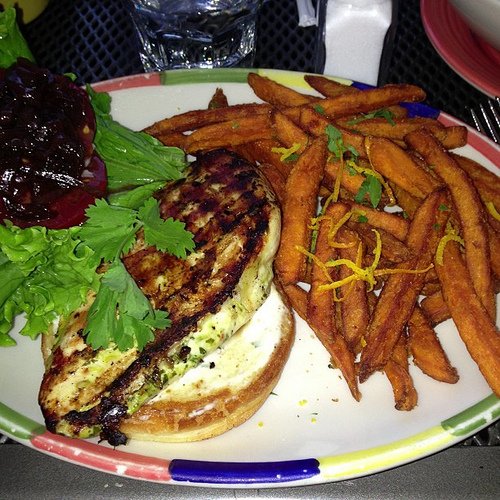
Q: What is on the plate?
A: The fries are on the plate.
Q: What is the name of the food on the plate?
A: The food is fries.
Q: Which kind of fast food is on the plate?
A: The food is fries.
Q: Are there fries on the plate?
A: Yes, there are fries on the plate.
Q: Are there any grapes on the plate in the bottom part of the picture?
A: No, there are fries on the plate.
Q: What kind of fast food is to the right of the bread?
A: The food is fries.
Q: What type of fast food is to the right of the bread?
A: The food is fries.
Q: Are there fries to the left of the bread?
A: No, the fries are to the right of the bread.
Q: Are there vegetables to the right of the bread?
A: No, there are fries to the right of the bread.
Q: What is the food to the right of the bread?
A: The food is fries.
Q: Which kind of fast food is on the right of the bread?
A: The food is fries.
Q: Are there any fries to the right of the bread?
A: Yes, there are fries to the right of the bread.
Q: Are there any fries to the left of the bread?
A: No, the fries are to the right of the bread.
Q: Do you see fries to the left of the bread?
A: No, the fries are to the right of the bread.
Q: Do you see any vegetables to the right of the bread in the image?
A: No, there are fries to the right of the bread.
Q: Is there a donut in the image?
A: No, there are no donuts.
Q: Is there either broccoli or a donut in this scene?
A: No, there are no donuts or broccoli.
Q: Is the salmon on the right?
A: Yes, the salmon is on the right of the image.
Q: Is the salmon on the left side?
A: No, the salmon is on the right of the image.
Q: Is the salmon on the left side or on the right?
A: The salmon is on the right of the image.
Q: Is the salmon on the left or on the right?
A: The salmon is on the right of the image.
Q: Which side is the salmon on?
A: The salmon is on the right of the image.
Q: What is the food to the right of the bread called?
A: The food is salmon.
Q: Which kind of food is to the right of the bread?
A: The food is salmon.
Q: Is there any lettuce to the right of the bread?
A: No, there is salmon to the right of the bread.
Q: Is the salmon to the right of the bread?
A: Yes, the salmon is to the right of the bread.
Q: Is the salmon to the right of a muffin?
A: No, the salmon is to the right of the bread.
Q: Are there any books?
A: No, there are no books.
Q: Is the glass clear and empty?
A: Yes, the glass is clear and empty.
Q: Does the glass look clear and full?
A: No, the glass is clear but empty.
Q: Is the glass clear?
A: Yes, the glass is clear.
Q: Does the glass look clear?
A: Yes, the glass is clear.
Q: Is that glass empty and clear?
A: Yes, the glass is empty and clear.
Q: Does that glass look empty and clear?
A: Yes, the glass is empty and clear.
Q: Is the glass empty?
A: Yes, the glass is empty.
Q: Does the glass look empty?
A: Yes, the glass is empty.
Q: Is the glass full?
A: No, the glass is empty.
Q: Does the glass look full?
A: No, the glass is empty.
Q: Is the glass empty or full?
A: The glass is empty.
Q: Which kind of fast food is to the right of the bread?
A: The food is fries.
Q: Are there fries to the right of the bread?
A: Yes, there are fries to the right of the bread.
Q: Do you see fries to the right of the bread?
A: Yes, there are fries to the right of the bread.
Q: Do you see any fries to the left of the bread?
A: No, the fries are to the right of the bread.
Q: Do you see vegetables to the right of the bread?
A: No, there are fries to the right of the bread.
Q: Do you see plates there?
A: Yes, there is a plate.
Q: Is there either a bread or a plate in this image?
A: Yes, there is a plate.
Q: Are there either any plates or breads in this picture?
A: Yes, there is a plate.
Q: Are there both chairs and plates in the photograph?
A: No, there is a plate but no chairs.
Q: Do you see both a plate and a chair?
A: No, there is a plate but no chairs.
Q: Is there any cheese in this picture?
A: No, there is no cheese.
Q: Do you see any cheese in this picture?
A: No, there is no cheese.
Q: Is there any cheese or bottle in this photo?
A: No, there are no cheese or bottles.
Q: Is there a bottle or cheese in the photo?
A: No, there are no cheese or bottles.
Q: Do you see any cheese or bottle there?
A: No, there are no cheese or bottles.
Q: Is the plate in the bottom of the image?
A: Yes, the plate is in the bottom of the image.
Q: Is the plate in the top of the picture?
A: No, the plate is in the bottom of the image.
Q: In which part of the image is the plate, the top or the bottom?
A: The plate is in the bottom of the image.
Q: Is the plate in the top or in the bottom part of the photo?
A: The plate is in the bottom of the image.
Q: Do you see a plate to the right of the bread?
A: Yes, there is a plate to the right of the bread.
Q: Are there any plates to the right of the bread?
A: Yes, there is a plate to the right of the bread.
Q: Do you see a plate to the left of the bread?
A: No, the plate is to the right of the bread.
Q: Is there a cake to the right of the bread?
A: No, there is a plate to the right of the bread.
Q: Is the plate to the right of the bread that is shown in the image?
A: Yes, the plate is to the right of the bread.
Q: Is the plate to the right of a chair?
A: No, the plate is to the right of the bread.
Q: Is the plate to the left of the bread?
A: No, the plate is to the right of the bread.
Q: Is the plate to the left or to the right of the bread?
A: The plate is to the right of the bread.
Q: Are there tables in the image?
A: Yes, there is a table.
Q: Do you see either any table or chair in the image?
A: Yes, there is a table.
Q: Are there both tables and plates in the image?
A: Yes, there are both a table and a plate.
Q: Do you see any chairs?
A: No, there are no chairs.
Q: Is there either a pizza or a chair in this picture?
A: No, there are no chairs or pizzas.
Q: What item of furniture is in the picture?
A: The piece of furniture is a table.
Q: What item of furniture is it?
A: The piece of furniture is a table.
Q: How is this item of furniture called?
A: This is a table.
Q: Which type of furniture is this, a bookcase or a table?
A: This is a table.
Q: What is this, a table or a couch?
A: This is a table.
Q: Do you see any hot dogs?
A: No, there are no hot dogs.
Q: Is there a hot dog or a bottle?
A: No, there are no hot dogs or bottles.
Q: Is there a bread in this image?
A: Yes, there is a bread.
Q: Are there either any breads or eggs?
A: Yes, there is a bread.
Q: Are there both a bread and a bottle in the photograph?
A: No, there is a bread but no bottles.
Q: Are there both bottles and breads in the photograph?
A: No, there is a bread but no bottles.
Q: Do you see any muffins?
A: No, there are no muffins.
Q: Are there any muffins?
A: No, there are no muffins.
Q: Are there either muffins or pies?
A: No, there are no muffins or pies.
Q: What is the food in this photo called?
A: The food is a bread.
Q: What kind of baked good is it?
A: The food is a bread.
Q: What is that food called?
A: That is a bread.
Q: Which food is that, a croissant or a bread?
A: That is a bread.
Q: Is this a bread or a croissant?
A: This is a bread.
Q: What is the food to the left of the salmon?
A: The food is a bread.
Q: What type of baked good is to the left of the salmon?
A: The food is a bread.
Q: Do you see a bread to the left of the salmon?
A: Yes, there is a bread to the left of the salmon.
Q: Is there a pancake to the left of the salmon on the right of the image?
A: No, there is a bread to the left of the salmon.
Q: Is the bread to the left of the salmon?
A: Yes, the bread is to the left of the salmon.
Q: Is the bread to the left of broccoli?
A: No, the bread is to the left of the salmon.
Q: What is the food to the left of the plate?
A: The food is a bread.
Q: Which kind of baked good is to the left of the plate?
A: The food is a bread.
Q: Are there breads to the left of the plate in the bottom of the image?
A: Yes, there is a bread to the left of the plate.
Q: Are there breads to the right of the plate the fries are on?
A: No, the bread is to the left of the plate.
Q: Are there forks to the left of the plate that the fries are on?
A: No, there is a bread to the left of the plate.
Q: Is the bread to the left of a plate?
A: Yes, the bread is to the left of a plate.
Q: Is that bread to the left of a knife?
A: No, the bread is to the left of a plate.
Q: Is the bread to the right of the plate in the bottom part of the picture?
A: No, the bread is to the left of the plate.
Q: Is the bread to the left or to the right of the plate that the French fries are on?
A: The bread is to the left of the plate.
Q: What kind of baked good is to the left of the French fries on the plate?
A: The food is a bread.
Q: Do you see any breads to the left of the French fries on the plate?
A: Yes, there is a bread to the left of the fries.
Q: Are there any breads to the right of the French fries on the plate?
A: No, the bread is to the left of the fries.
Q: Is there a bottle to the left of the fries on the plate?
A: No, there is a bread to the left of the fries.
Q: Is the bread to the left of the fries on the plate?
A: Yes, the bread is to the left of the fries.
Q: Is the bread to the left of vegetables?
A: No, the bread is to the left of the fries.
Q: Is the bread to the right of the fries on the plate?
A: No, the bread is to the left of the fries.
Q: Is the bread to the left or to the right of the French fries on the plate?
A: The bread is to the left of the French fries.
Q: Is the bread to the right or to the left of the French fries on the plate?
A: The bread is to the left of the French fries.